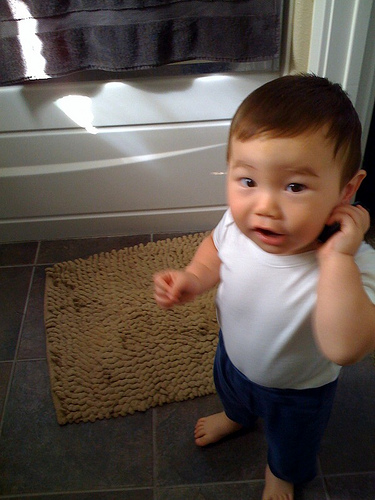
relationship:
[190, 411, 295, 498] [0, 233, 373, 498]
naked feet on ground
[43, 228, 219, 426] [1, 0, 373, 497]
mat in bathroom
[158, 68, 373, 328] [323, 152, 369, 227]
baby touching ear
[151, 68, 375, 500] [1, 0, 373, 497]
baby in bathroom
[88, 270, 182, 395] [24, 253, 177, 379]
mat on ground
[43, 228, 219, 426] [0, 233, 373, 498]
mat on ground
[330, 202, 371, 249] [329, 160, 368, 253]
hand by ear